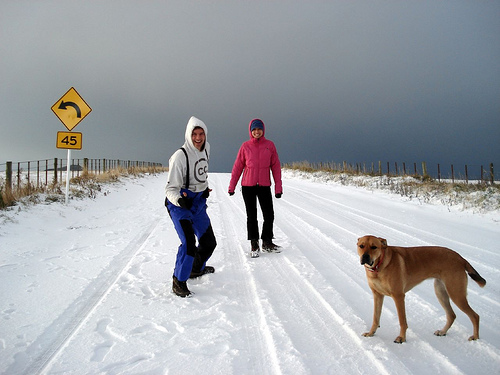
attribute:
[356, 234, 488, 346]
dog — brown, looking unhappy, standing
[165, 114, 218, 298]
man — standing, striking a pose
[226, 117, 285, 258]
woman — standing, smiling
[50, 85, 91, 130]
sign — yellow, black, signalling a turn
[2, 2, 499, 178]
sky — overcast, dark, gray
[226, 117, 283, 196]
jacket — pink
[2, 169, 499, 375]
ground — snow covered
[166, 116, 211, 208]
jacket — white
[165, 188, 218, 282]
pants — blue, black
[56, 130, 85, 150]
sign — yellow, stating speed limit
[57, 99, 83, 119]
arrow — black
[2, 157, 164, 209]
fence — lining the road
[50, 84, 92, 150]
signs — yellow, black